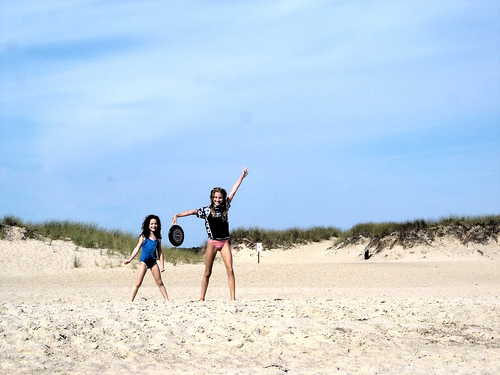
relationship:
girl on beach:
[104, 194, 176, 310] [306, 243, 481, 350]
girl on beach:
[171, 167, 249, 302] [1, 224, 499, 374]